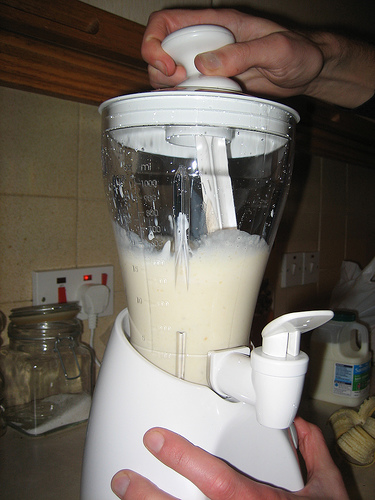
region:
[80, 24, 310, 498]
white glass and plastic blender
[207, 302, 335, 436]
white plastic blender spout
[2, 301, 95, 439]
glass canister of sugar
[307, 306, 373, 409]
plastic jug of white milk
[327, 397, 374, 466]
yellow banana peel on counter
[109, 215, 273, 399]
white liquid in white plastic blender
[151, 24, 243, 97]
white blender top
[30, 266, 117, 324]
white electric wall outlet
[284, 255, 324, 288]
white plastic electric wall switches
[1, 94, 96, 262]
wall tile on back of kitchen counter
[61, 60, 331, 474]
white blender in use for mixing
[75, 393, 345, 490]
fingers holding base of blender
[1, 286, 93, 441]
open glass container of white powder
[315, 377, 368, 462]
curled up peel of a banana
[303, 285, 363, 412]
white liquid in a plastic jug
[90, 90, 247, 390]
white liquid being stirred in blender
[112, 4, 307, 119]
hand curled around knob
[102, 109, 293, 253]
splatters on the top of container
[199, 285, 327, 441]
pour spout on the front of blender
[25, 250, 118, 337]
white plug in lighted socket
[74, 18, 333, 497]
a white juicing blender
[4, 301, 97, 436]
a clear glass container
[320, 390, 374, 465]
a banana peel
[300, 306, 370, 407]
a gallon milk carton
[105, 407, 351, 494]
a person's hand holding the juicer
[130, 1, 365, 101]
a person's hand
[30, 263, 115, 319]
an electrical wall outlet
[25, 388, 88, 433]
a small pile of sugar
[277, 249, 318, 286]
white wall light switches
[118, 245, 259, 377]
white blended fruit juice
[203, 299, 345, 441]
a white pouring nozzle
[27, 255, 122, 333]
a kitchen electrical outlet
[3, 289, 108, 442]
an open jar of sugar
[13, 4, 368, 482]
person making a snack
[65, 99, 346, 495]
a large white mixer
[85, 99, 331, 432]
a mixer full of smoothies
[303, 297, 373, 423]
a jug of milk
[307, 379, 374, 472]
a bunch of banana peels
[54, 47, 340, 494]
a small white blender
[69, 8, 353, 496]
person using a blender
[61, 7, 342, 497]
man preparing drink in a blender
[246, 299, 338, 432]
spigot of a blender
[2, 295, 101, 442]
glass jar on the counter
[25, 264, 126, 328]
white electrical outlet on wall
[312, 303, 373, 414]
bottle of milk on counter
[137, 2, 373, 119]
right hand of a man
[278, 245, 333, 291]
white switches on wall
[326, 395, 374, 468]
banana peel on counter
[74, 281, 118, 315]
white plug in outlet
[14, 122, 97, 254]
beige tile behind counter